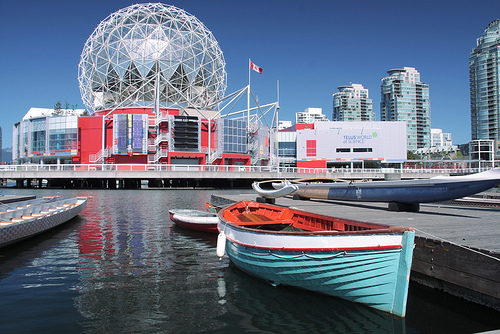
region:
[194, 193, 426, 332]
a boat next to a dock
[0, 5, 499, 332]
a city next to the ocean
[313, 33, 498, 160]
tall buildings in a city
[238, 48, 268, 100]
a white and red flag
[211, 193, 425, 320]
boat is color turquoise and red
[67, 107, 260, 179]
a red building in front body of water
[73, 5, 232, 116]
a big circle on top a building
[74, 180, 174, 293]
reflection of building on the water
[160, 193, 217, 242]
a small boat in the water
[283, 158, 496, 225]
a boat on the dock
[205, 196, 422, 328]
A blue boat with a red interior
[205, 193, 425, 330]
A wooden boat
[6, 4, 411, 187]
A modern design building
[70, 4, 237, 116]
A glass sphere building top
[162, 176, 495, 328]
A boat dock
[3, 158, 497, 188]
A railing in front of a building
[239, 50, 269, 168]
A Canadian flag on a pole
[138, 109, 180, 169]
A staircase on the side of a building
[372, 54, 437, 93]
The top of a building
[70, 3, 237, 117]
A geodesic dome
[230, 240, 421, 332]
Blue section painted on boat.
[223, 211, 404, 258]
White stripe on boat.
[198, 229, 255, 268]
White bumper on boat.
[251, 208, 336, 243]
Inside of boat is red.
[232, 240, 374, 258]
Red stripe on side of boat.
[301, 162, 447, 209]
Large canoe on pavement.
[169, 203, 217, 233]
Red and white boat in water.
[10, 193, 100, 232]
Large silver and white boat in water.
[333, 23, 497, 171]
Large buildings in background.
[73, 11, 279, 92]
Large white circle in background.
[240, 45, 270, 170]
The Canadian flag is red and white.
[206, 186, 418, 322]
The small boat is aqua, white, and red.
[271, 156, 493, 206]
A small boat is on the dock.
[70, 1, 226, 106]
A spherical building with glass windows.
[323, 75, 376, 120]
One high rise building.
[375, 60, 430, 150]
A second high rise building.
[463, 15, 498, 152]
A third high rise building.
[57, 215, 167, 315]
Reflections in the water.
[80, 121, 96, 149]
Part of the wall is red.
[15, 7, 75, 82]
The sky is blue.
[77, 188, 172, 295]
building reflected in water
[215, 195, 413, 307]
red, white, and blue boat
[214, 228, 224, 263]
floatation device on boat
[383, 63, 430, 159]
large blue building with many windows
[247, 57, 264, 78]
red and white Canadian flag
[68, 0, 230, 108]
large geometrical glass dome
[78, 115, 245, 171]
bright red building with many windows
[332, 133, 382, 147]
large sign on side of building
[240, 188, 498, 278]
docking area for boats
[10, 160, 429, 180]
long concrete walkway along buildings